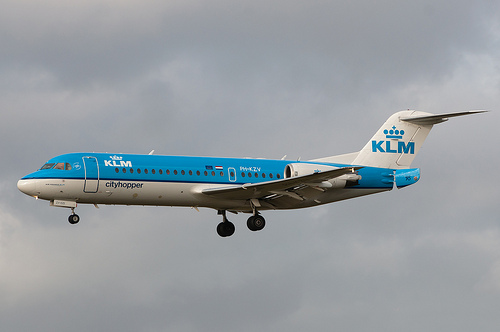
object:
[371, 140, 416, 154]
klm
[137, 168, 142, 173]
windows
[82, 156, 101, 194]
door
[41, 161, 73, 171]
windscreen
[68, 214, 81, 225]
gear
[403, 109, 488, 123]
rudder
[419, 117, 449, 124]
elevators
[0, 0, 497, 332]
sky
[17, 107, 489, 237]
airplane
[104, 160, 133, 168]
lettering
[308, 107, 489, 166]
tail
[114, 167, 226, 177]
row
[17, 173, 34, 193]
nose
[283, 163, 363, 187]
engine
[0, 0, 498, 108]
clouds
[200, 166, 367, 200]
wing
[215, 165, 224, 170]
flags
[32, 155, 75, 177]
cabin